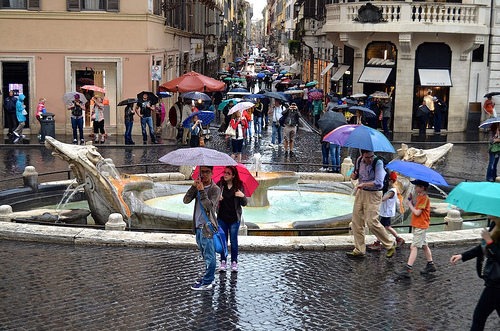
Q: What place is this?
A: It is a city.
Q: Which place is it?
A: It is a city.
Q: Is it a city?
A: Yes, it is a city.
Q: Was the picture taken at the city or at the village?
A: It was taken at the city.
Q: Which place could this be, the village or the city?
A: It is the city.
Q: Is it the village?
A: No, it is the city.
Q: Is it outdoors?
A: Yes, it is outdoors.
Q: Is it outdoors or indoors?
A: It is outdoors.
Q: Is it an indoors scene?
A: No, it is outdoors.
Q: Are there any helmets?
A: No, there are no helmets.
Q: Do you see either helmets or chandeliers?
A: No, there are no helmets or chandeliers.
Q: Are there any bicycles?
A: No, there are no bicycles.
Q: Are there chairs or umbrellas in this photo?
A: Yes, there is an umbrella.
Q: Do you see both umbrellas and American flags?
A: No, there is an umbrella but no American flags.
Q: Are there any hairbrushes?
A: No, there are no hairbrushes.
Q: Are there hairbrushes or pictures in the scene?
A: No, there are no hairbrushes or pictures.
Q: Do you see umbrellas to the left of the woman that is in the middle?
A: Yes, there is an umbrella to the left of the woman.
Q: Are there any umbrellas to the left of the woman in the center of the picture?
A: Yes, there is an umbrella to the left of the woman.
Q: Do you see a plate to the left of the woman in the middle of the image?
A: No, there is an umbrella to the left of the woman.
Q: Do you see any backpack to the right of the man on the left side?
A: No, there is an umbrella to the right of the man.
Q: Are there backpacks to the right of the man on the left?
A: No, there is an umbrella to the right of the man.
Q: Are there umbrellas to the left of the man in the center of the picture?
A: Yes, there is an umbrella to the left of the man.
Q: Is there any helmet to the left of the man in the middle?
A: No, there is an umbrella to the left of the man.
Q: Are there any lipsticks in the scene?
A: No, there are no lipsticks.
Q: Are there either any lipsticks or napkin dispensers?
A: No, there are no lipsticks or napkin dispensers.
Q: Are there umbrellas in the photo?
A: Yes, there is an umbrella.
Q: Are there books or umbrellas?
A: Yes, there is an umbrella.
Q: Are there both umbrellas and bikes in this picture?
A: No, there is an umbrella but no bikes.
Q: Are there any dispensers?
A: No, there are no dispensers.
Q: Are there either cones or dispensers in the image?
A: No, there are no dispensers or cones.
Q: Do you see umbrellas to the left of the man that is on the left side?
A: Yes, there is an umbrella to the left of the man.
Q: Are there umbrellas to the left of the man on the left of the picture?
A: Yes, there is an umbrella to the left of the man.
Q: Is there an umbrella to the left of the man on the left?
A: Yes, there is an umbrella to the left of the man.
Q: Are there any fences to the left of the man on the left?
A: No, there is an umbrella to the left of the man.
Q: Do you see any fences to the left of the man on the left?
A: No, there is an umbrella to the left of the man.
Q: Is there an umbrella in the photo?
A: Yes, there is an umbrella.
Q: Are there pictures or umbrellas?
A: Yes, there is an umbrella.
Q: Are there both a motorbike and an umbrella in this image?
A: No, there is an umbrella but no motorcycles.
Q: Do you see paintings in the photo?
A: No, there are no paintings.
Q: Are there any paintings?
A: No, there are no paintings.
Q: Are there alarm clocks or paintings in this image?
A: No, there are no paintings or alarm clocks.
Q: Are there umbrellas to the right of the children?
A: Yes, there is an umbrella to the right of the children.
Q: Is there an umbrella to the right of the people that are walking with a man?
A: Yes, there is an umbrella to the right of the children.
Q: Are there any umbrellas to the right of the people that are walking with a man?
A: Yes, there is an umbrella to the right of the children.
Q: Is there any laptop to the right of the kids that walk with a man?
A: No, there is an umbrella to the right of the children.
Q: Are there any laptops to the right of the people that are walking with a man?
A: No, there is an umbrella to the right of the children.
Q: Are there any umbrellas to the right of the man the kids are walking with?
A: Yes, there is an umbrella to the right of the man.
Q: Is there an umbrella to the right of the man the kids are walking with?
A: Yes, there is an umbrella to the right of the man.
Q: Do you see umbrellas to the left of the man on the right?
A: No, the umbrella is to the right of the man.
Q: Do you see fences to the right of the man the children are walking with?
A: No, there is an umbrella to the right of the man.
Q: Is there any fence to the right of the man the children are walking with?
A: No, there is an umbrella to the right of the man.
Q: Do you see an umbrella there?
A: Yes, there is an umbrella.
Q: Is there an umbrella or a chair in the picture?
A: Yes, there is an umbrella.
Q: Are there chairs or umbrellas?
A: Yes, there is an umbrella.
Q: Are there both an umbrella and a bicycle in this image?
A: No, there is an umbrella but no bicycles.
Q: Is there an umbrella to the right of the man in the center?
A: Yes, there is an umbrella to the right of the man.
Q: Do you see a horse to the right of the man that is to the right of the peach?
A: No, there is an umbrella to the right of the man.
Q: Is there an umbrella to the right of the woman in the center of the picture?
A: Yes, there is an umbrella to the right of the woman.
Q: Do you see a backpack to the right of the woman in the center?
A: No, there is an umbrella to the right of the woman.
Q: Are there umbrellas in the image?
A: Yes, there is an umbrella.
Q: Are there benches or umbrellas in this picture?
A: Yes, there is an umbrella.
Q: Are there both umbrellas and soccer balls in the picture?
A: No, there is an umbrella but no soccer balls.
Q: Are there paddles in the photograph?
A: No, there are no paddles.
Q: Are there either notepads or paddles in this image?
A: No, there are no paddles or notepads.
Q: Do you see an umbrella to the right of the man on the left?
A: Yes, there is an umbrella to the right of the man.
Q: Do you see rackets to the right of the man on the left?
A: No, there is an umbrella to the right of the man.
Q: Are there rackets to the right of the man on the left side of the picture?
A: No, there is an umbrella to the right of the man.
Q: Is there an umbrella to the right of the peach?
A: Yes, there is an umbrella to the right of the peach.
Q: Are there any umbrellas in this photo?
A: Yes, there is an umbrella.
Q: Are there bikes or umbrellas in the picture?
A: Yes, there is an umbrella.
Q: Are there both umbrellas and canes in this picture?
A: No, there is an umbrella but no canes.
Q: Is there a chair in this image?
A: No, there are no chairs.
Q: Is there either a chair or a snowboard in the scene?
A: No, there are no chairs or snowboards.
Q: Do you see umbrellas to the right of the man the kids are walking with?
A: Yes, there is an umbrella to the right of the man.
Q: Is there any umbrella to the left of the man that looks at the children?
A: No, the umbrella is to the right of the man.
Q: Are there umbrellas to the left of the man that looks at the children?
A: No, the umbrella is to the right of the man.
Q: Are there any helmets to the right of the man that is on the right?
A: No, there is an umbrella to the right of the man.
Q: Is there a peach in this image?
A: Yes, there is a peach.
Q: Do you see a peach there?
A: Yes, there is a peach.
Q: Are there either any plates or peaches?
A: Yes, there is a peach.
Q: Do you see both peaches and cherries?
A: No, there is a peach but no cherries.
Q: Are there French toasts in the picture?
A: No, there are no French toasts.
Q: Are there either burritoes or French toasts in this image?
A: No, there are no French toasts or burritoes.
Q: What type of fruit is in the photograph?
A: The fruit is a peach.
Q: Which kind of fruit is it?
A: The fruit is a peach.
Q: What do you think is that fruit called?
A: This is a peach.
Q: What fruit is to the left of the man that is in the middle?
A: The fruit is a peach.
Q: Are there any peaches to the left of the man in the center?
A: Yes, there is a peach to the left of the man.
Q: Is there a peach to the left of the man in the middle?
A: Yes, there is a peach to the left of the man.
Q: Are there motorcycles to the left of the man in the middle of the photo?
A: No, there is a peach to the left of the man.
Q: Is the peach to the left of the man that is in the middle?
A: Yes, the peach is to the left of the man.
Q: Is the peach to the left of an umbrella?
A: Yes, the peach is to the left of an umbrella.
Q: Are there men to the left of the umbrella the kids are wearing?
A: Yes, there is a man to the left of the umbrella.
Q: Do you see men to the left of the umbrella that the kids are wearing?
A: Yes, there is a man to the left of the umbrella.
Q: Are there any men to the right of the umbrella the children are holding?
A: No, the man is to the left of the umbrella.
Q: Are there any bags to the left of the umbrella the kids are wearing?
A: No, there is a man to the left of the umbrella.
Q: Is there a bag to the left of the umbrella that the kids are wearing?
A: No, there is a man to the left of the umbrella.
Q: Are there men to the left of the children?
A: Yes, there is a man to the left of the children.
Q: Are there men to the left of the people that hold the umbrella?
A: Yes, there is a man to the left of the children.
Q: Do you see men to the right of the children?
A: No, the man is to the left of the children.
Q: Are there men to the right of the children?
A: No, the man is to the left of the children.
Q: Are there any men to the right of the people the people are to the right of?
A: No, the man is to the left of the children.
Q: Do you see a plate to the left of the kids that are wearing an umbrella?
A: No, there is a man to the left of the kids.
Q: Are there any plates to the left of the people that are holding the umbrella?
A: No, there is a man to the left of the kids.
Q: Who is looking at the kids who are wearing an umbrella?
A: The man is looking at the children.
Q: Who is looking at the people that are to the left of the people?
A: The man is looking at the children.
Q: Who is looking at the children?
A: The man is looking at the children.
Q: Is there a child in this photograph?
A: Yes, there are children.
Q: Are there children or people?
A: Yes, there are children.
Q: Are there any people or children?
A: Yes, there are children.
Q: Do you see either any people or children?
A: Yes, there are children.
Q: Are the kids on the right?
A: Yes, the kids are on the right of the image.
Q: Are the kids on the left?
A: No, the kids are on the right of the image.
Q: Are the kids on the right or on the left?
A: The kids are on the right of the image.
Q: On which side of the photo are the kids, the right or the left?
A: The kids are on the right of the image.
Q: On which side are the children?
A: The children are on the right of the image.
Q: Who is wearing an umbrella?
A: The kids are wearing an umbrella.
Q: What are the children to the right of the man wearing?
A: The children are wearing an umbrella.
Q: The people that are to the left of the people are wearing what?
A: The children are wearing an umbrella.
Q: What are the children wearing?
A: The children are wearing an umbrella.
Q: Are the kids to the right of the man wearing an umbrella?
A: Yes, the children are wearing an umbrella.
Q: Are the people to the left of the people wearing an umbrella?
A: Yes, the children are wearing an umbrella.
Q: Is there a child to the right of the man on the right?
A: Yes, there are children to the right of the man.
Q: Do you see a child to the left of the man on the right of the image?
A: No, the children are to the right of the man.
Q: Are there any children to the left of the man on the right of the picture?
A: No, the children are to the right of the man.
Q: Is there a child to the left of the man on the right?
A: No, the children are to the right of the man.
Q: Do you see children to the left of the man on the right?
A: No, the children are to the right of the man.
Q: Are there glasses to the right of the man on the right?
A: No, there are children to the right of the man.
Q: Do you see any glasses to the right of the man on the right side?
A: No, there are children to the right of the man.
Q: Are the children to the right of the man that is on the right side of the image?
A: Yes, the children are to the right of the man.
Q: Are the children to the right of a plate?
A: No, the children are to the right of the man.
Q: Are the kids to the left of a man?
A: No, the kids are to the right of a man.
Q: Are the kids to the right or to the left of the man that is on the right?
A: The kids are to the right of the man.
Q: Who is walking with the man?
A: The children are walking with the man.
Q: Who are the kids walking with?
A: The kids are walking with a man.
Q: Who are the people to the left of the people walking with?
A: The kids are walking with a man.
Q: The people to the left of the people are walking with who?
A: The kids are walking with a man.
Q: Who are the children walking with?
A: The kids are walking with a man.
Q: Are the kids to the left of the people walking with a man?
A: Yes, the children are walking with a man.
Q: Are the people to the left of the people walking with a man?
A: Yes, the children are walking with a man.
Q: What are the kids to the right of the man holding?
A: The kids are holding the umbrella.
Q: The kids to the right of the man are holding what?
A: The kids are holding the umbrella.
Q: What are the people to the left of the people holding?
A: The kids are holding the umbrella.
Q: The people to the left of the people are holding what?
A: The kids are holding the umbrella.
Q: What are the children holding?
A: The kids are holding the umbrella.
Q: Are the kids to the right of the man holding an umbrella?
A: Yes, the children are holding an umbrella.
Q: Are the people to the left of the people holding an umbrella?
A: Yes, the children are holding an umbrella.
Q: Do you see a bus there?
A: No, there are no buses.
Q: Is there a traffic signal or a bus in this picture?
A: No, there are no buses or traffic lights.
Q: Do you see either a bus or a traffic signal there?
A: No, there are no buses or traffic lights.